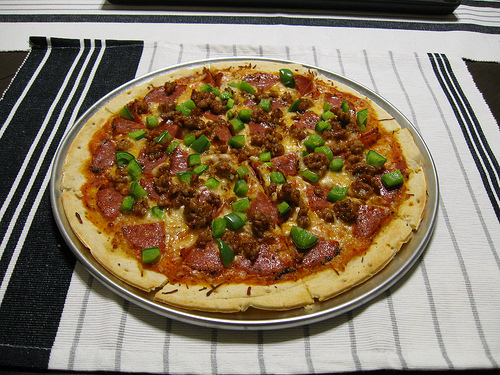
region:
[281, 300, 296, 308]
THE CRUST IS BROWN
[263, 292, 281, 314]
THE CRUST IS BROWN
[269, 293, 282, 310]
THE CRUST IS BROWN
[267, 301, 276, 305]
THE CRUST IS BROWN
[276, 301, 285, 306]
THE CRUST IS BROWN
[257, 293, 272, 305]
THE CRUST IS BROWN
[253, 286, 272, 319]
THE CRUST IS BROWN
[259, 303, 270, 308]
THE CRUST IS BROWN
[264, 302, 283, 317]
THE CRUST IS BROWN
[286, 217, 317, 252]
Green peppers on a pizza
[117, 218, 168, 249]
Pepperoni on a pizza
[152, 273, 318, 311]
Sliced crust of a pizza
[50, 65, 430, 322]
Pizza in a pizza pan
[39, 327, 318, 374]
Striped pattern on a tablecloth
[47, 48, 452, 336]
Pizza sitting on a table top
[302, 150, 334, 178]
Sausage as topping on pizza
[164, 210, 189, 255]
Cheese as topping on pizza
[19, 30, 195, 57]
Curled edge of tablecloth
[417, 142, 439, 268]
Pizza pan holding a pizza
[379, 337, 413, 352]
the table cloth is stripe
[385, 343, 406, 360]
the table cloth is stripe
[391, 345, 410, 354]
the table cloth is stripe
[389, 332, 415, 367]
the table cloth is stripe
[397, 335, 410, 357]
the table cloth is stripe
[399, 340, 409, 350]
the table cloth is stripe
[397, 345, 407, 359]
the table cloth is stripe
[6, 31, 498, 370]
black and white placemat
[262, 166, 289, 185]
piece of green pepper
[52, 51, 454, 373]
place mat has black stripes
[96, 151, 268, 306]
pizza has red sauce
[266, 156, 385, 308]
pizza has a bit of cheese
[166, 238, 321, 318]
pizza has this crust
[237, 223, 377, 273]
pepperoni is greasy and shiny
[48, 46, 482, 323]
pizza has a lot of meat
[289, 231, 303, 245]
the chillies are green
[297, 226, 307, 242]
the chillies are green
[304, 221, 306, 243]
the chillies are green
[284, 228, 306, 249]
the chillies are green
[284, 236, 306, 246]
the chillies are green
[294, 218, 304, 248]
the chillies are green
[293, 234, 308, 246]
the chillies are green